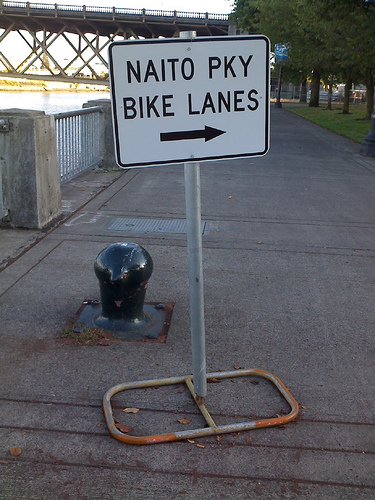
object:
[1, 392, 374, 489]
grooves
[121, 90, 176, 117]
bike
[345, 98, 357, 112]
ground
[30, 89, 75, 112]
water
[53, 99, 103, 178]
fence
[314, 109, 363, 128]
grass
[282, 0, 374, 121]
trees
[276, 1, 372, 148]
park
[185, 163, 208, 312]
stand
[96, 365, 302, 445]
stand bottom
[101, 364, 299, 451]
stand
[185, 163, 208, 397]
pole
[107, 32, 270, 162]
sign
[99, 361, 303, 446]
base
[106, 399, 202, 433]
leaves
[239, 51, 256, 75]
y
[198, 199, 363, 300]
pavement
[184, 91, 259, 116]
word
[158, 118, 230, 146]
arrow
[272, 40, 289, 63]
sign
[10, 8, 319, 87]
bridge